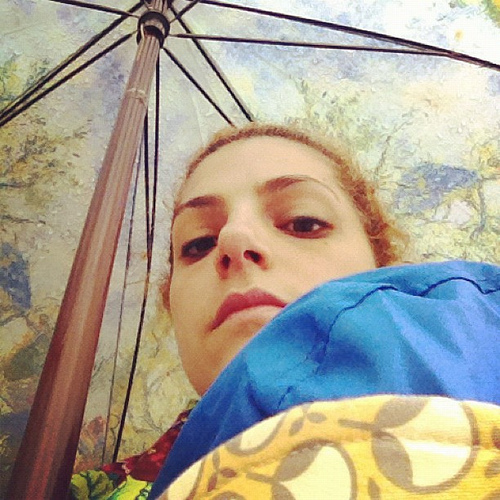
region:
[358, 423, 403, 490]
brown leaf on fabric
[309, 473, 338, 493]
solid yellow color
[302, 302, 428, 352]
lines in blue cloth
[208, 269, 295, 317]
red lipstick on woman's lip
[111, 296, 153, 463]
wire frame on umbrella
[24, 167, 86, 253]
rain drops on umbrella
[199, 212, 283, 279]
woman's pointy nose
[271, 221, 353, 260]
small lines under woman's eye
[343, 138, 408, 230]
stray blond hair on woman's head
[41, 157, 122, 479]
dark brown umbrella frame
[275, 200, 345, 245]
Brown eye looking down.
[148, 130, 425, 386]
Woman with red hair.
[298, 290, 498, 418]
Blue shirt.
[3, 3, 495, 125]
Large decorative umbrella.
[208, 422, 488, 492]
Yellow patterned fabric with stitching.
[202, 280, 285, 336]
Female lips with no lipstick.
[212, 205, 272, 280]
Female nose, fair-skinned.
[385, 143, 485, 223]
Blue painted flower pattern.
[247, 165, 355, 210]
Thin brown female eyebrow.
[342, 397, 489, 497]
Flower black and white fabric pattern.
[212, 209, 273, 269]
Nose of a woman holding an umbrella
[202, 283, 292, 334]
Lips of a female looking at the camera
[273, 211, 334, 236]
left eyeball and eyelid of a woman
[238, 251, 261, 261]
Woman's left nostril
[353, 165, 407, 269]
Light colored pieces of woman's hair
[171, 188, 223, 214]
Right eyebrow of woman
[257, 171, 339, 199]
Woman's left eyebrow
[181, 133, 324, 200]
Forehead on a woman looking at the camera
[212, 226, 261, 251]
Tip of this woman's nose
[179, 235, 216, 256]
Right eye of a woman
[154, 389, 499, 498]
Yellow and brown section of a jacket.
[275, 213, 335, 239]
Female brown eye.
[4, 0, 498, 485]
Colorful spread open umbrella.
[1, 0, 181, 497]
Brown stem to umbrella.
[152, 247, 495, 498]
Blue puffy material with seam showing.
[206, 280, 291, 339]
Female top lip shaded pink.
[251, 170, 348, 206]
Light brown arched eyebrow.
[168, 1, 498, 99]
Black stems inside umbrella.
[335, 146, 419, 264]
Light brown curly hair.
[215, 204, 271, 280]
Female Caucasian pointy nose.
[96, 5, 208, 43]
Joint of open umbrella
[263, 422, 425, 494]
Yellow flowered patterned blanket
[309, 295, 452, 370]
Shoulder of blue coat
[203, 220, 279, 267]
Pointed nose on girls face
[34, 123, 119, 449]
Pole of open umbrella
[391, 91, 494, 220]
design on opened umbrella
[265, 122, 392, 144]
Redish hair on top of head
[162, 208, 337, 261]
Two dark brown eyes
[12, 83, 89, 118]
Black arms of open umbrella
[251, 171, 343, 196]
Eyebrow on girls face